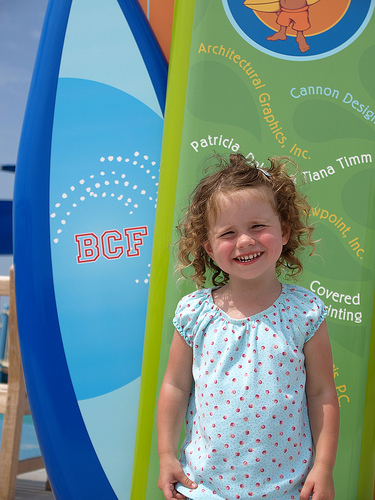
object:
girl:
[149, 133, 348, 500]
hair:
[170, 147, 318, 299]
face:
[208, 186, 284, 286]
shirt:
[167, 282, 330, 498]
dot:
[244, 427, 251, 436]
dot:
[278, 472, 285, 479]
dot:
[222, 325, 227, 333]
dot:
[304, 320, 311, 328]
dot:
[209, 464, 217, 473]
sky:
[2, 1, 52, 171]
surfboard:
[13, 1, 167, 497]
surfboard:
[127, 1, 374, 499]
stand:
[0, 264, 52, 499]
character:
[263, 0, 323, 63]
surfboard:
[139, 1, 173, 67]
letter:
[72, 228, 101, 266]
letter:
[99, 225, 124, 262]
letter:
[124, 224, 148, 259]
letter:
[289, 86, 301, 100]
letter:
[190, 138, 201, 154]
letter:
[197, 41, 207, 56]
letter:
[309, 279, 321, 293]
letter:
[335, 156, 345, 171]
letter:
[258, 91, 272, 105]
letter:
[342, 90, 354, 105]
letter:
[350, 240, 361, 253]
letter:
[289, 143, 298, 153]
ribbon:
[256, 165, 271, 178]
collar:
[205, 283, 291, 326]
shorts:
[274, 5, 311, 33]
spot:
[107, 155, 115, 163]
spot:
[140, 188, 146, 195]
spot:
[50, 211, 57, 219]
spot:
[70, 184, 77, 193]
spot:
[133, 149, 139, 157]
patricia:
[189, 130, 241, 155]